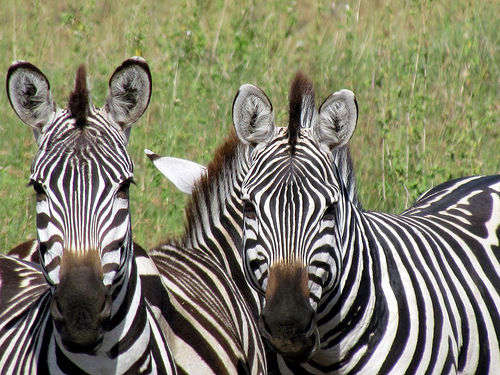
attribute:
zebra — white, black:
[228, 84, 497, 373]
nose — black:
[257, 267, 318, 337]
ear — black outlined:
[12, 62, 52, 140]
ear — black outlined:
[101, 47, 155, 125]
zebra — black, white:
[6, 56, 266, 372]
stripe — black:
[353, 212, 407, 372]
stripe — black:
[361, 206, 437, 373]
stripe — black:
[133, 257, 263, 373]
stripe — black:
[426, 186, 498, 286]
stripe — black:
[299, 206, 379, 320]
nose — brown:
[255, 257, 320, 340]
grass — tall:
[1, 6, 499, 267]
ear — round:
[104, 52, 160, 126]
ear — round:
[6, 63, 64, 141]